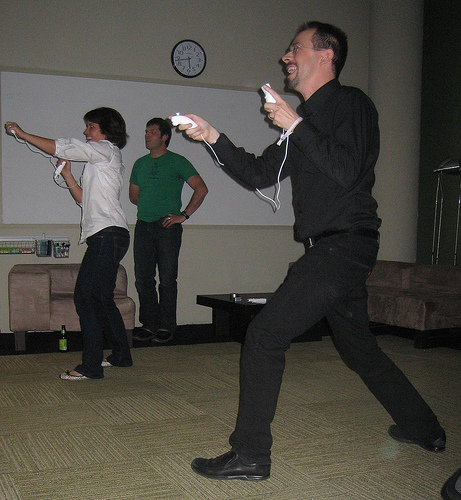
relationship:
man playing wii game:
[173, 10, 448, 484] [163, 79, 278, 134]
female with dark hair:
[5, 106, 140, 380] [83, 106, 130, 150]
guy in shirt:
[128, 117, 207, 345] [121, 143, 204, 225]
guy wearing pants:
[128, 117, 207, 345] [131, 218, 185, 333]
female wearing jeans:
[5, 106, 140, 380] [73, 225, 132, 379]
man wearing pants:
[166, 20, 449, 484] [228, 237, 442, 452]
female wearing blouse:
[5, 106, 140, 380] [54, 138, 130, 246]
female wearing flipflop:
[5, 106, 140, 380] [57, 370, 95, 380]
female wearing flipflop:
[5, 106, 140, 380] [95, 358, 113, 366]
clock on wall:
[167, 33, 210, 79] [2, 4, 404, 349]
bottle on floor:
[56, 322, 70, 354] [5, 326, 457, 496]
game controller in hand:
[171, 113, 196, 129] [260, 82, 300, 129]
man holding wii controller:
[173, 10, 448, 484] [166, 110, 199, 133]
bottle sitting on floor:
[58, 324, 68, 353] [5, 326, 457, 496]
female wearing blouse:
[5, 106, 140, 380] [36, 129, 121, 237]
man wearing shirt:
[173, 10, 448, 484] [204, 77, 383, 244]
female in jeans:
[5, 106, 140, 380] [78, 247, 124, 351]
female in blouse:
[5, 106, 140, 380] [54, 138, 130, 246]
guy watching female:
[127, 117, 207, 341] [5, 106, 140, 380]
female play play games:
[5, 106, 140, 380] [31, 94, 413, 241]